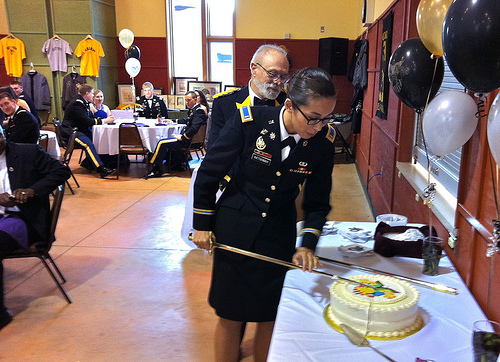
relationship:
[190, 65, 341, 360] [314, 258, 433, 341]
officer cutting cake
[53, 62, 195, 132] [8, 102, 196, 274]
people sitting at tables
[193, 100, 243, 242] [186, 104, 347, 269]
sleeve on jacket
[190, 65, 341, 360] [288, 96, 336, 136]
officer wearing glasses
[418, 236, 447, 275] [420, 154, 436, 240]
cup holding balloon strings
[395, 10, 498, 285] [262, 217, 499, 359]
centerpiece on table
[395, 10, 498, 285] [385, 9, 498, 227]
centerpiece made of balloons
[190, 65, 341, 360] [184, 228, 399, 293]
officer using sword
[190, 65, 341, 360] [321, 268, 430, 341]
officer cutting cake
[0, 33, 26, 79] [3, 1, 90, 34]
jersey hanging on wall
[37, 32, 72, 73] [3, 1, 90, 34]
jersey hanging on wall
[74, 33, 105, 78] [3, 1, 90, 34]
jersey hanging on wall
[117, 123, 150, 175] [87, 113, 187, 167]
chair at table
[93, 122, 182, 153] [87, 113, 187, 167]
tablecloth on table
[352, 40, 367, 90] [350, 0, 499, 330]
black backpack hanging on wall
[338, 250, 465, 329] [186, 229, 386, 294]
cake cut with knife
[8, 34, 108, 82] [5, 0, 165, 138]
shirts on wall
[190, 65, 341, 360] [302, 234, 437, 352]
officer cutting cake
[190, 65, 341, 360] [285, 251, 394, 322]
officer using knife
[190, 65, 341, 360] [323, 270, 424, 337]
officer having cake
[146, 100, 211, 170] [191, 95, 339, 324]
men in uniform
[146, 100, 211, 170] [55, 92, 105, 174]
men in uniform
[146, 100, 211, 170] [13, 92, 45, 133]
men in uniform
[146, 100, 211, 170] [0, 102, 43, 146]
men in uniform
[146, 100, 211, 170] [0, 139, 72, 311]
men in uniform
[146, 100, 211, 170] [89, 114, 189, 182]
men sitting at table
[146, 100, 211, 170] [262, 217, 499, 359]
men sitting at table